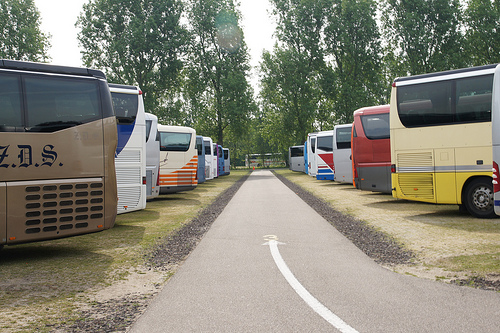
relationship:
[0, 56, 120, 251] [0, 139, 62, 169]
rv has initials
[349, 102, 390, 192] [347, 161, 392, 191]
vehicle has fender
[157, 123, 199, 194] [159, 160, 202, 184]
bus has orange stripes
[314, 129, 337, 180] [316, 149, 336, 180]
bus has stripes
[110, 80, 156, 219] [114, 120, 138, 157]
white rv has blue stripe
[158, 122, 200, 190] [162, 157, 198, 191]
bus has stripes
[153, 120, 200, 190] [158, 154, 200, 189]
bus with stripes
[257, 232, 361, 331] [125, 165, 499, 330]
white arrow in road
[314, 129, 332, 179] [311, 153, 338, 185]
bus with markings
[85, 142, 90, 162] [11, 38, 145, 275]
paint on bus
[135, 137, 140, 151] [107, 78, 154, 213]
paint on bus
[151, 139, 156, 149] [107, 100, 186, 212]
paint on bus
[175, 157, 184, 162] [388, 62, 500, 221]
paint on rv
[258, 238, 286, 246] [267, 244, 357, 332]
white arrow on line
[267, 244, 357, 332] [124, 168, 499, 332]
line on road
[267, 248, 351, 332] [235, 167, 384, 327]
line in street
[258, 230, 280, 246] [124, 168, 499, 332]
number three on road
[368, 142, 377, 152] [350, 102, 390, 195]
paint on vehicle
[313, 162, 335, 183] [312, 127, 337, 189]
paint on bus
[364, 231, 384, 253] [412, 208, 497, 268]
rocks by grass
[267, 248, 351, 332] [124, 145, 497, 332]
line on road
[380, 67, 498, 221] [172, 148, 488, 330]
rv near road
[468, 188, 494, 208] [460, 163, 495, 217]
rim on tire